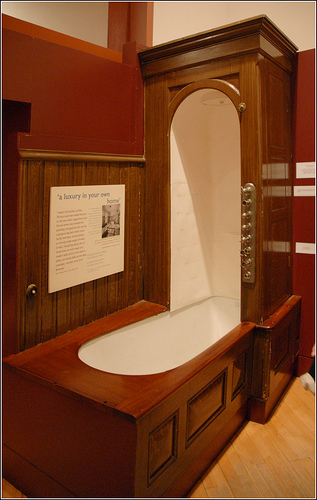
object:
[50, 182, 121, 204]
words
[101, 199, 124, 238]
picture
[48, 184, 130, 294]
sign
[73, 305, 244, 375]
bathtub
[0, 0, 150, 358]
wall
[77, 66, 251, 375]
shower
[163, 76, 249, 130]
arch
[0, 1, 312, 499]
wood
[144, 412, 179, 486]
panels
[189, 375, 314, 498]
floor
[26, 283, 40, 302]
knob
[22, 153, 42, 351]
panel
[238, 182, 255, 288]
nozzles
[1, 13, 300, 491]
frame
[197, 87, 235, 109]
circle